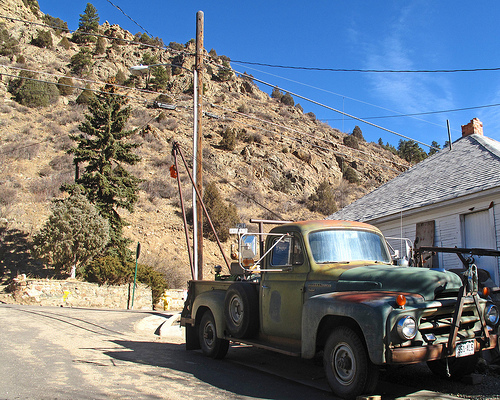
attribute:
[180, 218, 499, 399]
truck — parked, old, large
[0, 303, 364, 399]
dirt — brown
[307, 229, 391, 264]
windshield — shiny, dirty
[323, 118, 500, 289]
building — old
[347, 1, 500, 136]
cloud — white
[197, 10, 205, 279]
pole — green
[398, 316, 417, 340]
light — circular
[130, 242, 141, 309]
stop sign — green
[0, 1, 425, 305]
hill — rocky, elevated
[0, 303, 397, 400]
road — dirty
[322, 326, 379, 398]
front tire — black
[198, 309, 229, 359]
rear tire — black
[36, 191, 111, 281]
tree — small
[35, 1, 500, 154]
blue sky — clear